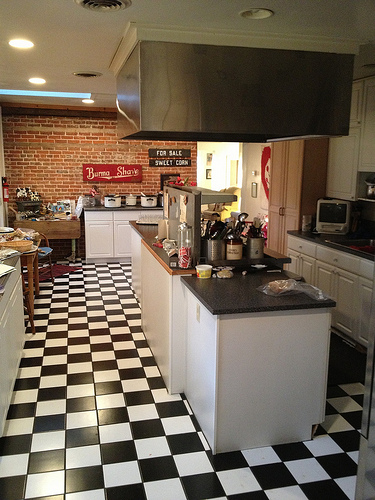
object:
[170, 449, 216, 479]
tile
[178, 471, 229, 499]
tile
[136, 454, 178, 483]
tile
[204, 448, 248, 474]
tile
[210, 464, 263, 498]
tile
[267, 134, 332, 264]
cupboard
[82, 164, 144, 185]
sign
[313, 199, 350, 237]
tv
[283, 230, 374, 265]
counter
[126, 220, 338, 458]
island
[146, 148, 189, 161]
sign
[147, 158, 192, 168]
sign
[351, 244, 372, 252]
cloth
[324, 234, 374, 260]
sink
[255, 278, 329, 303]
bag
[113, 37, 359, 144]
vent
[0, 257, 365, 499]
floor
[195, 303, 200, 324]
receptacle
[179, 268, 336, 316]
counter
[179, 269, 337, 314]
countertop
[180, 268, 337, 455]
cabinet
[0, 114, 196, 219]
wall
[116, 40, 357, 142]
duct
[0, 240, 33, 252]
basket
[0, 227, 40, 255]
tabletop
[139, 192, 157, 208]
pot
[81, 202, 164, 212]
counter top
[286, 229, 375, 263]
countertop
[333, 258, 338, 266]
handle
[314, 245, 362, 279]
drawer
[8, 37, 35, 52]
spotlight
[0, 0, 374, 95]
ceiling